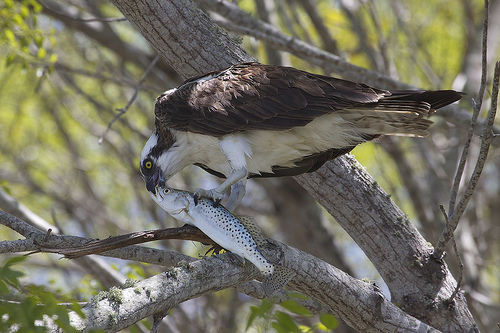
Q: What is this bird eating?
A: Fish.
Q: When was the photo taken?
A: Daytime.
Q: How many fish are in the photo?
A: 1.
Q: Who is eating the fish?
A: The bird.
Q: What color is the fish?
A: Silver.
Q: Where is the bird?
A: In a tree.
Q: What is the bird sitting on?
A: A branch.